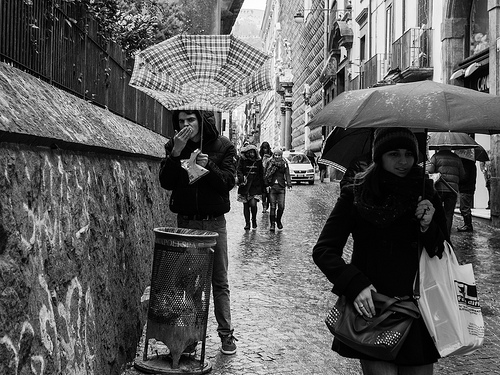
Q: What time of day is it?
A: Day time.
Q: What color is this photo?
A: Black and white.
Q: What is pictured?
A: City people.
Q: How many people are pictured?
A: 7.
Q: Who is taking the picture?
A: Photographer.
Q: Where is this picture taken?
A: On the sidewalk.